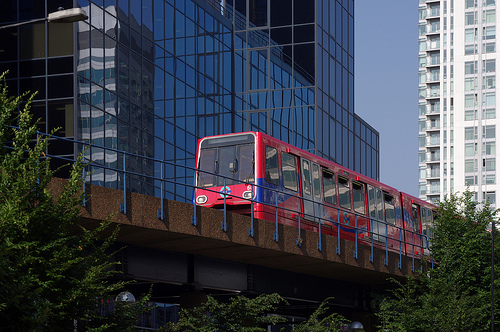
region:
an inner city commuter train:
[195, 129, 443, 264]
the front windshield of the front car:
[197, 133, 254, 185]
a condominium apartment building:
[417, 1, 498, 204]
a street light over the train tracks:
[0, 6, 89, 31]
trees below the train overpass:
[0, 231, 497, 331]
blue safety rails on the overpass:
[83, 141, 252, 236]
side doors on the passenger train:
[299, 154, 324, 224]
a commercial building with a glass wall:
[0, 0, 380, 132]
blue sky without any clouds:
[355, 1, 417, 114]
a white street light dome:
[115, 290, 137, 304]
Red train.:
[196, 129, 498, 264]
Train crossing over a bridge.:
[3, 106, 496, 288]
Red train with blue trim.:
[192, 129, 499, 276]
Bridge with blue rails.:
[1, 116, 454, 283]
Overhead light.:
[3, 6, 91, 35]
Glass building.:
[2, 1, 378, 181]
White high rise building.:
[417, 1, 499, 229]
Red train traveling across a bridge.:
[1, 117, 498, 284]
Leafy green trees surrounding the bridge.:
[0, 58, 497, 330]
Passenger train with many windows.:
[190, 131, 497, 267]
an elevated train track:
[18, 140, 444, 295]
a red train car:
[192, 130, 397, 256]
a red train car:
[400, 185, 485, 271]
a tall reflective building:
[0, 0, 370, 245]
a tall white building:
[412, 2, 497, 202]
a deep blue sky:
[346, 0, 421, 187]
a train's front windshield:
[195, 140, 252, 185]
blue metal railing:
[40, 137, 435, 273]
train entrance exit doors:
[300, 157, 321, 218]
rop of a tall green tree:
[380, 195, 492, 325]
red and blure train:
[198, 118, 438, 245]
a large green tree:
[2, 110, 172, 324]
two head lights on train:
[163, 185, 253, 209]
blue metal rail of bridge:
[37, 180, 367, 234]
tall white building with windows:
[408, 71, 486, 223]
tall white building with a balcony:
[418, 67, 490, 214]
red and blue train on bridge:
[86, 153, 437, 290]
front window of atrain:
[182, 133, 260, 191]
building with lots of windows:
[87, 80, 377, 230]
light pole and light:
[3, 3, 90, 69]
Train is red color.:
[187, 130, 447, 247]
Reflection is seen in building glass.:
[65, 1, 172, 171]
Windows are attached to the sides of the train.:
[280, 155, 420, 230]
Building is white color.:
[420, 25, 497, 185]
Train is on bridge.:
[85, 136, 380, 271]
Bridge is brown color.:
[102, 195, 262, 265]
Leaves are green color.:
[12, 160, 97, 298]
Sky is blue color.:
[370, 7, 420, 139]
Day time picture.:
[18, 33, 478, 314]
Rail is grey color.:
[71, 148, 192, 202]